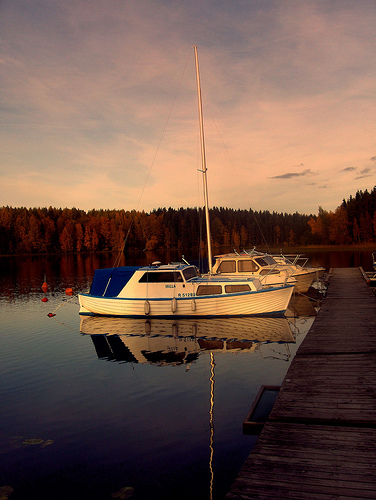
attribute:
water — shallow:
[2, 245, 331, 499]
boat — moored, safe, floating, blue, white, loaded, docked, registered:
[77, 259, 295, 318]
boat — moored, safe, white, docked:
[201, 257, 319, 299]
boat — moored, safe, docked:
[272, 252, 328, 271]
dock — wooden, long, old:
[225, 267, 375, 498]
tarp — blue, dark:
[88, 265, 147, 299]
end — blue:
[74, 261, 141, 325]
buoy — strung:
[38, 278, 51, 290]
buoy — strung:
[60, 286, 76, 299]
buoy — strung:
[38, 295, 51, 304]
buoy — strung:
[45, 310, 55, 318]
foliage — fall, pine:
[2, 206, 374, 246]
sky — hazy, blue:
[1, 1, 375, 215]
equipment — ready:
[258, 263, 293, 284]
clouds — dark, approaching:
[266, 150, 375, 193]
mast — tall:
[192, 41, 214, 277]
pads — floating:
[10, 433, 55, 453]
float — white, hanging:
[187, 299, 199, 313]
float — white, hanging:
[169, 296, 181, 315]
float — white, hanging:
[141, 298, 151, 316]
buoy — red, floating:
[41, 278, 50, 292]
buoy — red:
[64, 285, 72, 295]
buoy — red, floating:
[40, 296, 50, 303]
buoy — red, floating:
[47, 311, 56, 319]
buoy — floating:
[64, 287, 75, 298]